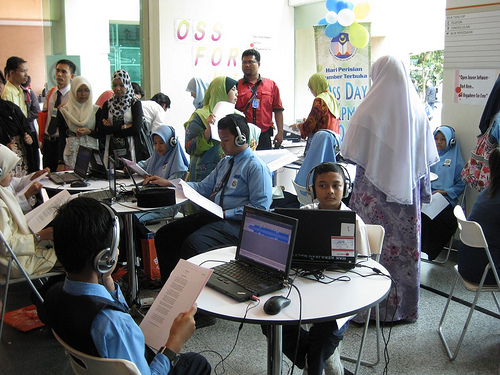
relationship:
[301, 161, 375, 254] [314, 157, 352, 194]
child has headphones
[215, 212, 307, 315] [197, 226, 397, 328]
laptop on table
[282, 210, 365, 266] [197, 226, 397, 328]
laptop on table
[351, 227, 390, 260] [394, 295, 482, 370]
chair on floor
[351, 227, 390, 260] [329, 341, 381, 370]
chair has base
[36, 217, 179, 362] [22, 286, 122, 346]
boy wears vest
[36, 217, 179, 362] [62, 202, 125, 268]
boy wears headphones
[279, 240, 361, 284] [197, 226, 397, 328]
cables on table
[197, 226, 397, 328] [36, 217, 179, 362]
table near boy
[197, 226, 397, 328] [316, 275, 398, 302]
table has edge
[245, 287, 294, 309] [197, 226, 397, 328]
mouse on table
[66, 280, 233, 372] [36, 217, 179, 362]
clothes on boy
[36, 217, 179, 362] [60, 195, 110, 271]
boy has head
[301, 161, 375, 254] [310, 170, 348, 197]
boy has face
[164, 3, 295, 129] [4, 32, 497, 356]
wall behind people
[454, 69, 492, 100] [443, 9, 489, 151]
paper on wall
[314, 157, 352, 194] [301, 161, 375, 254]
headphones on boy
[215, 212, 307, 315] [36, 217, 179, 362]
laptop near boy